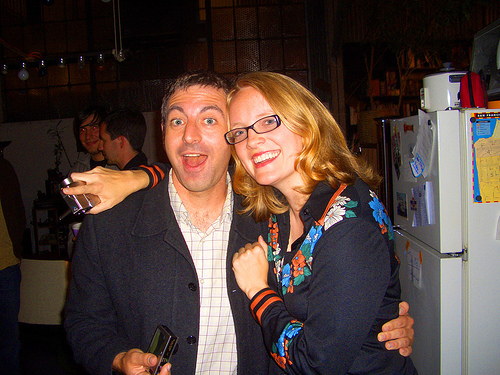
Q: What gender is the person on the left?
A: Male.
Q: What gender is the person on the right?
A: Female.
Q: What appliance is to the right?
A: Refrigerator.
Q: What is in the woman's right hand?
A: Camera.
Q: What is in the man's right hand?
A: Camera.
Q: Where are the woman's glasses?
A: On her face.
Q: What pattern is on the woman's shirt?
A: Floral.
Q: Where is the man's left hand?
A: Around the woman's waist.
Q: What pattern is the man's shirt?
A: Checkered.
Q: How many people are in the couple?
A: Two.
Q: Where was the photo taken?
A: Party.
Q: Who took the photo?
A: Friend.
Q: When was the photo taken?
A: Night.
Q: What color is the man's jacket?
A: Black.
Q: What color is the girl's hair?
A: Blonde.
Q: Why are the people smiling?
A: Happy.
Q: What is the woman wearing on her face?
A: Glasses.